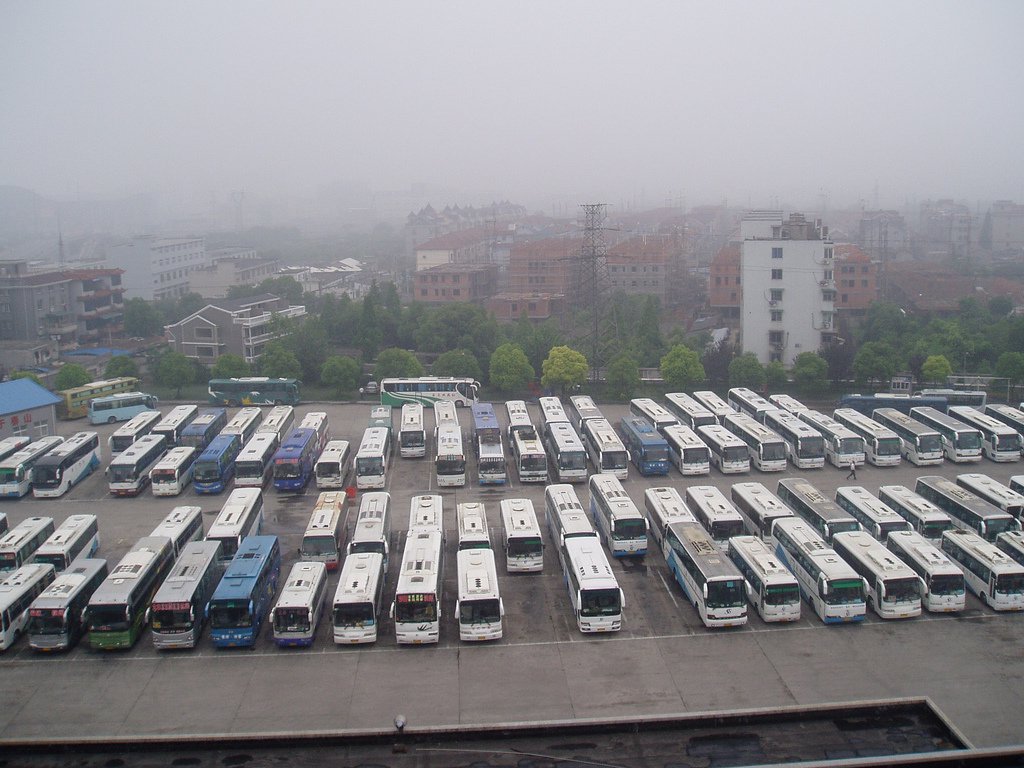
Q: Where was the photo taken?
A: Above a parking lot.